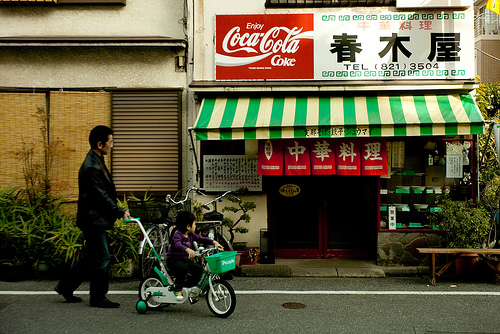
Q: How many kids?
A: One.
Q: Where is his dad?
A: Pushing the bike.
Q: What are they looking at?
A: The store.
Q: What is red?
A: The sign.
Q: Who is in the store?
A: People.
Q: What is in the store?
A: Food.